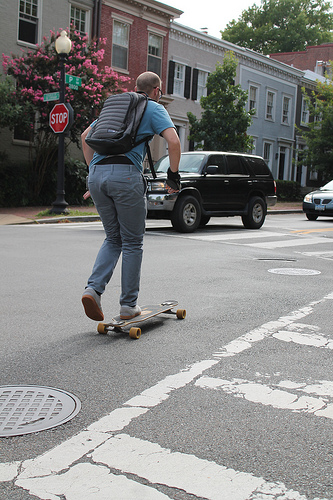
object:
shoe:
[80, 287, 103, 321]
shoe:
[119, 299, 140, 319]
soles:
[80, 293, 104, 322]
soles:
[119, 313, 142, 318]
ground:
[0, 208, 333, 469]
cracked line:
[193, 298, 333, 446]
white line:
[13, 431, 328, 500]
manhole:
[0, 382, 82, 441]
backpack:
[84, 89, 148, 156]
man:
[79, 71, 181, 324]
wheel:
[128, 327, 141, 341]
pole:
[51, 52, 69, 209]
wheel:
[177, 309, 187, 319]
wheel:
[97, 323, 108, 334]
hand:
[164, 166, 180, 194]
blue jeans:
[84, 156, 147, 308]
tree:
[0, 17, 134, 202]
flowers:
[0, 19, 134, 127]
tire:
[242, 195, 265, 228]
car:
[142, 149, 278, 232]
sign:
[48, 102, 69, 133]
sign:
[63, 71, 82, 91]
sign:
[43, 91, 60, 101]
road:
[0, 224, 333, 456]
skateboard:
[96, 299, 187, 339]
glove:
[165, 166, 180, 190]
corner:
[6, 207, 92, 226]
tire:
[171, 191, 201, 233]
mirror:
[204, 165, 219, 176]